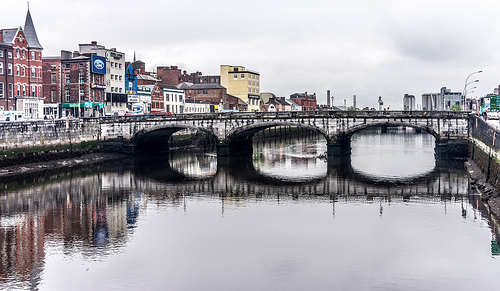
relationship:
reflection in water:
[127, 156, 477, 223] [3, 124, 495, 286]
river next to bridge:
[0, 127, 500, 291] [193, 104, 488, 141]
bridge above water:
[96, 103, 471, 169] [3, 124, 495, 286]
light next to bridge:
[465, 64, 480, 105] [97, 105, 474, 175]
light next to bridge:
[463, 70, 482, 110] [97, 105, 474, 175]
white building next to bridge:
[93, 44, 126, 96] [0, 107, 500, 138]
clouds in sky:
[0, 0, 498, 90] [1, 0, 499, 108]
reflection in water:
[0, 140, 500, 290] [3, 124, 495, 286]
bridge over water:
[79, 110, 474, 175] [116, 143, 498, 290]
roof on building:
[23, 1, 43, 49] [4, 34, 41, 95]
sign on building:
[84, 55, 110, 74] [56, 49, 104, 122]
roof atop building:
[20, 0, 42, 50] [11, 30, 42, 104]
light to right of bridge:
[463, 70, 482, 110] [95, 109, 469, 163]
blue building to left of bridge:
[124, 60, 139, 99] [100, 112, 470, 168]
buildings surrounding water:
[3, 19, 472, 109] [1, 106, 498, 288]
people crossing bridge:
[384, 103, 391, 113] [94, 110, 473, 155]